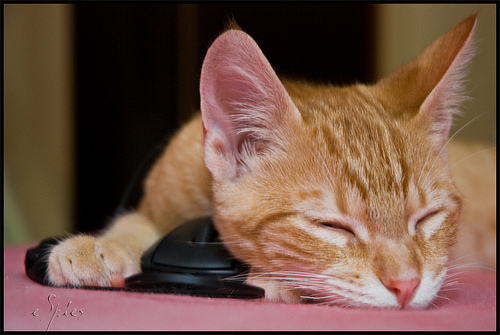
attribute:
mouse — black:
[139, 207, 270, 277]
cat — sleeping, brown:
[49, 10, 496, 307]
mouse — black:
[125, 213, 263, 297]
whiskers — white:
[220, 252, 495, 317]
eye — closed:
[412, 203, 447, 232]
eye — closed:
[306, 218, 358, 242]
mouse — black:
[132, 207, 316, 334]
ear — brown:
[413, 15, 482, 131]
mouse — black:
[137, 214, 249, 278]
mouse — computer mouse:
[140, 209, 252, 288]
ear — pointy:
[181, 32, 288, 158]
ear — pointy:
[396, 47, 470, 141]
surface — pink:
[5, 232, 498, 325]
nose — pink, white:
[379, 264, 438, 322]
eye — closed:
[408, 197, 449, 234]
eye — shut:
[409, 201, 445, 231]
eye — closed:
[306, 213, 360, 243]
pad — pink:
[1, 240, 495, 329]